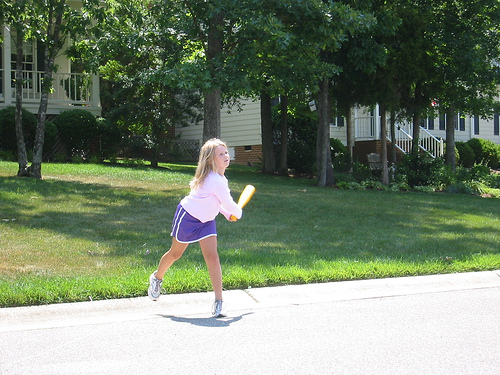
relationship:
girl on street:
[144, 137, 248, 318] [1, 265, 500, 374]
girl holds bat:
[144, 137, 248, 318] [230, 181, 258, 224]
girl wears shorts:
[144, 137, 248, 318] [169, 202, 221, 244]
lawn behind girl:
[1, 157, 500, 311] [144, 137, 248, 318]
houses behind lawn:
[1, 1, 108, 163] [1, 157, 500, 311]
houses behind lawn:
[132, 0, 500, 191] [1, 157, 500, 311]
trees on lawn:
[1, 1, 108, 163] [1, 157, 500, 311]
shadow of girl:
[155, 307, 257, 328] [144, 137, 248, 318]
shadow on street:
[155, 307, 257, 328] [1, 265, 500, 374]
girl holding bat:
[144, 137, 248, 318] [230, 181, 258, 224]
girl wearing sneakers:
[144, 137, 248, 318] [210, 296, 223, 318]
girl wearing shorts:
[144, 137, 248, 318] [169, 202, 221, 244]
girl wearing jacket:
[144, 137, 248, 318] [184, 170, 242, 223]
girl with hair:
[144, 137, 248, 318] [188, 137, 231, 189]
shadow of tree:
[2, 171, 499, 273] [2, 0, 85, 179]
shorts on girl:
[169, 202, 221, 244] [144, 137, 248, 318]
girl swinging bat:
[144, 137, 248, 318] [230, 181, 258, 224]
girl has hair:
[144, 137, 248, 318] [188, 137, 231, 189]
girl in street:
[144, 137, 248, 318] [1, 265, 500, 374]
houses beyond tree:
[1, 1, 108, 163] [2, 0, 85, 179]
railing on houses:
[1, 66, 93, 104] [1, 1, 108, 163]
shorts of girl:
[169, 202, 221, 244] [144, 137, 248, 318]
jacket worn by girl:
[184, 170, 242, 223] [144, 137, 248, 318]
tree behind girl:
[2, 0, 85, 179] [144, 137, 248, 318]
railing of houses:
[1, 66, 93, 104] [1, 1, 108, 163]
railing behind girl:
[1, 66, 93, 104] [144, 137, 248, 318]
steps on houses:
[382, 112, 447, 184] [132, 0, 500, 191]